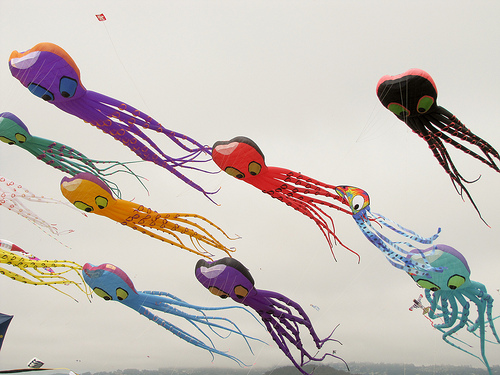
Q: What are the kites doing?
A: Flying.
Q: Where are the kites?
A: In the sky.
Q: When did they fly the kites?
A: During the competition.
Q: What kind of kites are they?
A: Octopus.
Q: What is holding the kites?
A: String.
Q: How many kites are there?
A: 10.